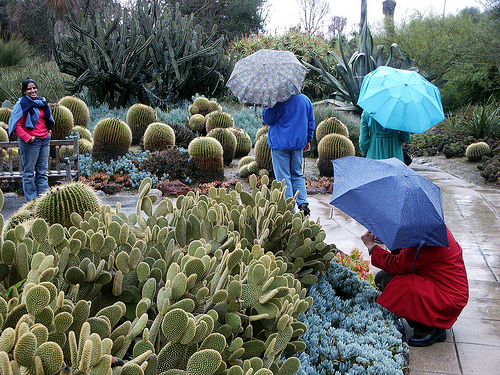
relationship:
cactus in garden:
[177, 138, 220, 183] [42, 40, 393, 364]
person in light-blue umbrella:
[358, 108, 411, 166] [356, 65, 445, 134]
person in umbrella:
[260, 82, 313, 219] [356, 65, 444, 131]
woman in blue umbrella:
[10, 63, 50, 200] [327, 149, 461, 250]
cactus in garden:
[156, 302, 198, 349] [0, 97, 262, 186]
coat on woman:
[371, 229, 469, 330] [345, 151, 497, 352]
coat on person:
[373, 229, 468, 330] [359, 215, 471, 347]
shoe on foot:
[411, 322, 445, 346] [410, 322, 455, 354]